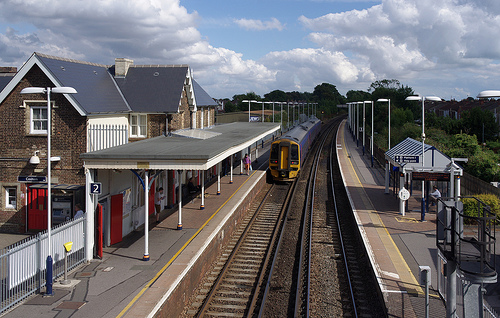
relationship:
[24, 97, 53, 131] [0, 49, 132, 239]
window on side of building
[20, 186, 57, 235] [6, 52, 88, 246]
red door on building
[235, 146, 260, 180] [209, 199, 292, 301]
person standing on tracks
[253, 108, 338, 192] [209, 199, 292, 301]
train on tracks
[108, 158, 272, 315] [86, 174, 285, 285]
line on ground